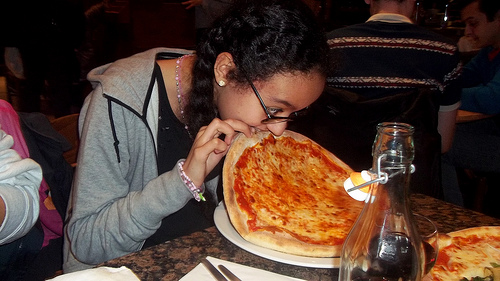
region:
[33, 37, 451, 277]
a woman eating a pizza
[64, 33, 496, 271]
a girl eating a cheese pizza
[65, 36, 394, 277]
a girl eatting an uncut pizza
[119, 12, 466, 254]
a girl eating an uncut cheese pizza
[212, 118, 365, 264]
an uncut cheese pizza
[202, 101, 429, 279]
an uncut cooked pizza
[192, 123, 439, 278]
an uncut cooked cheese pizza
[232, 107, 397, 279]
an uncut baked pizza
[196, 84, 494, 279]
an uncut baked pizza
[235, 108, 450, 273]
a cooked cheese pizza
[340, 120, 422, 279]
A bottle with liquid inside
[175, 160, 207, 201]
A wristband worn by a lady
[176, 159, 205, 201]
A bracelet worn on a wrist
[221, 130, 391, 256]
Pizza being consumed by a lady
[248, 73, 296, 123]
Glasses worn by a girl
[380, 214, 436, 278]
A glass of red wine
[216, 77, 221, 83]
An earing worn by a girl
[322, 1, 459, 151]
A man sitting at a table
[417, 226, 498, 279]
Freshly cooked pizza on a table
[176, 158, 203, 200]
A pink bracelet on someone's wrist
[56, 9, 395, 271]
a girl eating pizza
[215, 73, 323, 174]
a girl biting into a pizza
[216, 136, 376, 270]
a tomato and cheese pizza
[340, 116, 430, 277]
an empty glass bottle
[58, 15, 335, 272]
a girl wearing a gray jacket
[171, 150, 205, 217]
a white and purple wrist band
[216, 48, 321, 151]
a girl wearing glasses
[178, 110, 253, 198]
the hand of a girl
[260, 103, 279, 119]
the eye of a girl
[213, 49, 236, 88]
the ear of a girl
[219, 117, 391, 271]
the pizza has cheese on it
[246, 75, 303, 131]
the girl is wearing glasses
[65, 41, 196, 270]
the girl's sweater is gray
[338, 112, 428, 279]
a glass bottle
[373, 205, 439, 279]
a glass of wine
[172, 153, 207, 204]
a bracelet on the wrist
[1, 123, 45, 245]
part of the sweater is white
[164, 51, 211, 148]
the girl is wearing a necklace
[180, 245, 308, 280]
silverware on a napkin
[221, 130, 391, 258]
A big cheese pizza.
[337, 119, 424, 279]
A bottle on the table.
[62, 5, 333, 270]
A girl eating pizza.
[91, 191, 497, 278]
A marble like table.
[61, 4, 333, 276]
A girl with glasses on.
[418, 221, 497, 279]
Half a pizza on a table.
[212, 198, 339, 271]
A white plate on a table.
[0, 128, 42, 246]
Part of an arm.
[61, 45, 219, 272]
A gray hoodie shirt.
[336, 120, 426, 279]
A clear glass bottle.